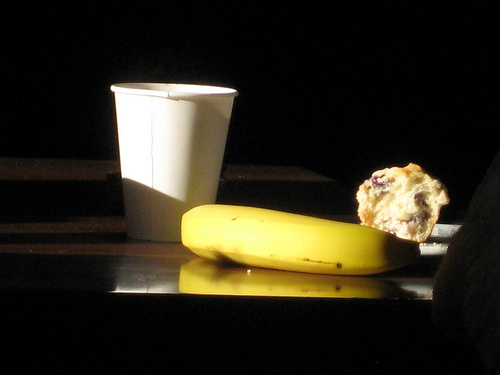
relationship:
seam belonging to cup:
[147, 90, 156, 240] [110, 78, 240, 242]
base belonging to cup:
[124, 229, 181, 241] [110, 78, 240, 242]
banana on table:
[179, 203, 419, 276] [8, 178, 484, 349]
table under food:
[101, 248, 181, 318] [167, 159, 447, 289]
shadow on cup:
[123, 171, 187, 242] [104, 82, 238, 252]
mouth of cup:
[103, 75, 237, 105] [106, 66, 240, 244]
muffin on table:
[353, 163, 449, 244] [2, 165, 482, 341]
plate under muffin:
[416, 223, 462, 256] [352, 157, 452, 242]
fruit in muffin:
[370, 169, 392, 189] [353, 163, 449, 244]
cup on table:
[106, 66, 240, 244] [6, 177, 474, 316]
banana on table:
[179, 195, 428, 284] [3, 167, 482, 298]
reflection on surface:
[154, 253, 397, 315] [11, 202, 472, 325]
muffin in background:
[353, 163, 449, 244] [10, 76, 469, 264]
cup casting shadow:
[109, 82, 240, 244] [11, 216, 191, 308]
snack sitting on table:
[100, 71, 464, 281] [2, 165, 482, 341]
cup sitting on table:
[106, 66, 240, 244] [2, 165, 482, 341]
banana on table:
[179, 203, 419, 276] [8, 177, 478, 331]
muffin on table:
[351, 155, 444, 255] [2, 165, 482, 341]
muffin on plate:
[353, 163, 449, 244] [330, 195, 450, 243]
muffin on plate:
[353, 163, 449, 244] [412, 223, 457, 252]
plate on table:
[430, 228, 447, 288] [8, 148, 437, 335]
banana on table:
[179, 203, 419, 276] [3, 159, 418, 297]